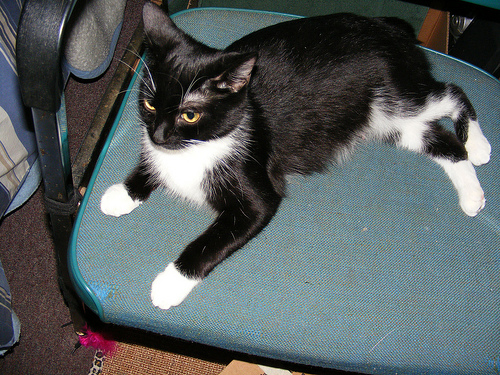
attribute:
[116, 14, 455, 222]
cat — black, resting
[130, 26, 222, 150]
head — black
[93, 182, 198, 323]
paws — white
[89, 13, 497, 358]
seat — blue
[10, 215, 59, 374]
carpet — gray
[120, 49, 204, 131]
whiskers — white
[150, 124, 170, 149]
nose — black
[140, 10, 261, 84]
wears — black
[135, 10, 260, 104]
ears — black